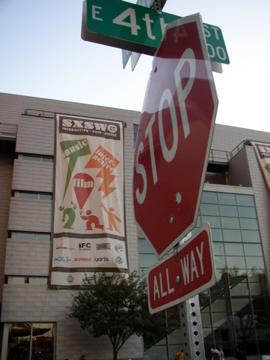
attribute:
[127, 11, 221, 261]
sign — red, stop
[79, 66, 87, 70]
sky — white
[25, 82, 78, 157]
rail — silver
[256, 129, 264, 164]
poster — hanging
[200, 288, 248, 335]
window — glass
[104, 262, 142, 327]
tree — green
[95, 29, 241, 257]
stop sign — red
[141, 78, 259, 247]
stop sign — red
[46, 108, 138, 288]
ad — giant